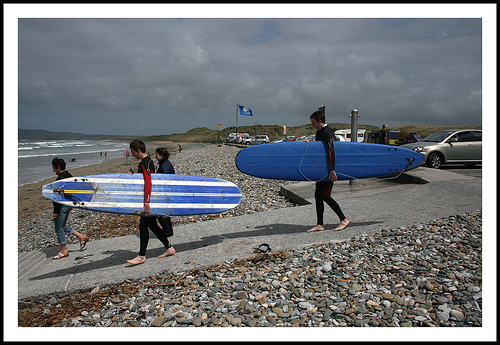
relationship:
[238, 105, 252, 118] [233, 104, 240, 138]
flag on pole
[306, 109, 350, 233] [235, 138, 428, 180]
man holding surfboard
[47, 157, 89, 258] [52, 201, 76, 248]
person wearing jeans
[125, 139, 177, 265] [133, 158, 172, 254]
man wearing wet suit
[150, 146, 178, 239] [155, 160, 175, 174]
woman wearing shirt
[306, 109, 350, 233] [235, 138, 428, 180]
man carrying surfboard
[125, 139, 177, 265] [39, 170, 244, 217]
man carrying surfboard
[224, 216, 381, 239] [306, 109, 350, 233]
shadow of man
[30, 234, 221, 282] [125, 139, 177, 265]
shadow of man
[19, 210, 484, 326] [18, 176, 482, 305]
rocks next to walkway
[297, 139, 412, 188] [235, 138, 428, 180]
leash on surfboard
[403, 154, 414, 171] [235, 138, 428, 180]
leash holder on surfboard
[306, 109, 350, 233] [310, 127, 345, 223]
man wearing wet suit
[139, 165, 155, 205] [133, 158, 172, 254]
sleeve on wet suit